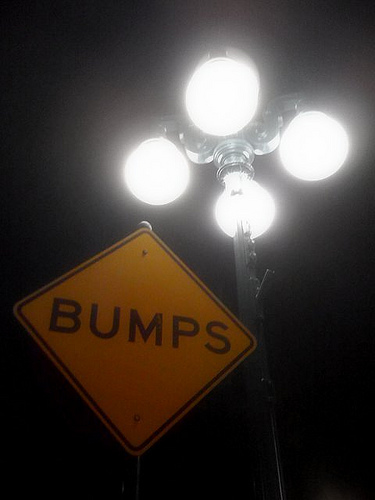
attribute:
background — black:
[175, 418, 255, 483]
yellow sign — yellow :
[64, 293, 231, 372]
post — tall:
[279, 112, 349, 181]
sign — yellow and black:
[13, 225, 257, 453]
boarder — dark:
[12, 228, 256, 456]